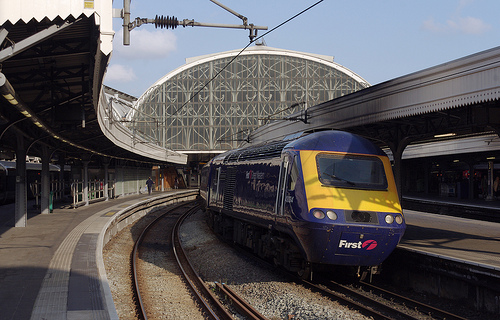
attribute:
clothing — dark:
[146, 177, 153, 189]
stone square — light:
[48, 231, 105, 301]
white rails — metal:
[82, 179, 109, 206]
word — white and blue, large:
[337, 237, 364, 250]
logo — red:
[361, 236, 377, 250]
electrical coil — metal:
[152, 12, 181, 32]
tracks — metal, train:
[130, 198, 467, 318]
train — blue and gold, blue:
[191, 121, 413, 291]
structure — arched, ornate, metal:
[123, 46, 370, 155]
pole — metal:
[124, 12, 286, 57]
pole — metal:
[31, 137, 61, 231]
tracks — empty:
[81, 174, 269, 318]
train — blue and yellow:
[234, 132, 404, 286]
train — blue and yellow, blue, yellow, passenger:
[196, 128, 405, 284]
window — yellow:
[314, 151, 389, 191]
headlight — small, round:
[324, 206, 337, 223]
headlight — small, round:
[384, 213, 393, 223]